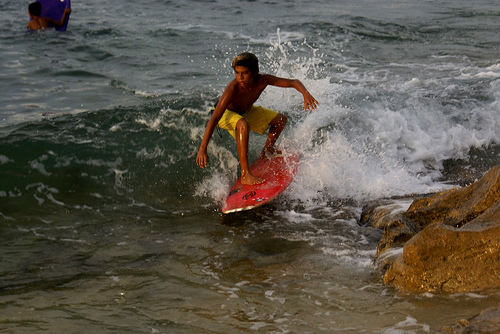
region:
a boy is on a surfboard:
[185, 46, 319, 220]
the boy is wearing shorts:
[220, 102, 277, 144]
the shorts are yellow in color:
[213, 102, 285, 139]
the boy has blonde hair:
[231, 50, 258, 79]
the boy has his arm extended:
[188, 59, 247, 168]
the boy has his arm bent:
[264, 65, 324, 112]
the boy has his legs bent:
[219, 95, 302, 186]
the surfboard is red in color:
[218, 140, 308, 217]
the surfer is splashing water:
[201, 51, 437, 203]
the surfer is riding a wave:
[193, 47, 328, 221]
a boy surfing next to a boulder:
[149, 15, 499, 290]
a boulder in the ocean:
[341, 106, 489, 311]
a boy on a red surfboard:
[149, 35, 329, 234]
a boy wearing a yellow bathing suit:
[161, 53, 317, 179]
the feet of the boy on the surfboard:
[223, 135, 303, 222]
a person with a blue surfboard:
[18, 0, 84, 44]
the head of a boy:
[223, 48, 263, 91]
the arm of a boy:
[263, 65, 333, 116]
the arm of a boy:
[191, 100, 229, 173]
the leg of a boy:
[223, 115, 265, 186]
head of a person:
[220, 42, 275, 95]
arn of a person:
[200, 90, 234, 134]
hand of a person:
[183, 138, 219, 173]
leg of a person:
[223, 127, 256, 177]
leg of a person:
[254, 110, 300, 150]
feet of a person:
[233, 162, 270, 183]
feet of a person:
[260, 140, 299, 157]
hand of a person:
[193, 153, 222, 170]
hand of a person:
[303, 96, 326, 110]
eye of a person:
[228, 65, 258, 77]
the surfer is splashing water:
[202, 51, 326, 220]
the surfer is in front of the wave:
[201, 54, 326, 221]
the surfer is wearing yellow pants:
[222, 97, 272, 142]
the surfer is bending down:
[196, 56, 321, 189]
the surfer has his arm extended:
[184, 77, 244, 171]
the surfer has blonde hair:
[233, 47, 263, 74]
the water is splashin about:
[220, 33, 442, 214]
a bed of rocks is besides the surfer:
[372, 155, 499, 330]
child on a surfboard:
[196, 28, 298, 230]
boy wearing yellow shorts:
[196, 100, 284, 141]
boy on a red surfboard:
[216, 135, 303, 225]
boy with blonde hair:
[218, 43, 270, 86]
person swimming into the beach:
[23, 6, 85, 29]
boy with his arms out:
[194, 54, 319, 170]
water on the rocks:
[352, 159, 494, 326]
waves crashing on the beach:
[36, 103, 466, 193]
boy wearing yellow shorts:
[208, 98, 279, 140]